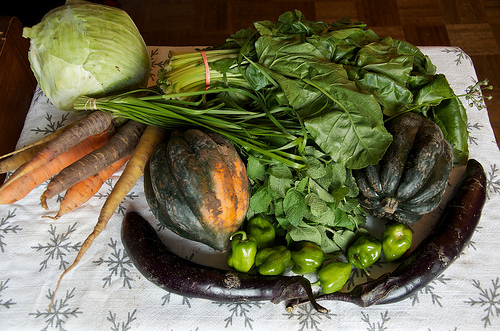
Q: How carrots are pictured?
A: 7.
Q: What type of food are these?
A: Vegetables.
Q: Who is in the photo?
A: No one.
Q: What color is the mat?
A: White and green.